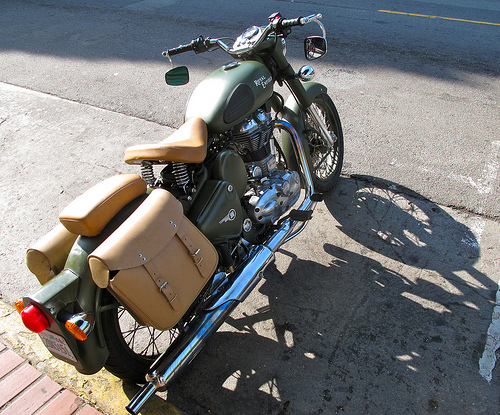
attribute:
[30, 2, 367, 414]
motorcycle — parked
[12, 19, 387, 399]
motorcycle — parked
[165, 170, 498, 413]
shadow — motorbike's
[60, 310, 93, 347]
light — black, orange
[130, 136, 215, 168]
motorbike seat — brown, leather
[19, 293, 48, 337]
light — red, rear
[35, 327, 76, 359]
license plate — white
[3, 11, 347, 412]
motorcycle — parked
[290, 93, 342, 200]
tire — black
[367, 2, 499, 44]
line — yellow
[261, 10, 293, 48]
light — orange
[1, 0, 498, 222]
road — black tar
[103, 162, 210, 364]
bag — light, brown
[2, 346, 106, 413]
brick pathway — red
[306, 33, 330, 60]
mirrors — side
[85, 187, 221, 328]
bag — brown, tied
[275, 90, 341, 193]
tire — round